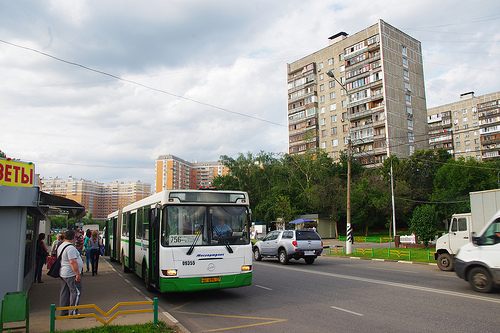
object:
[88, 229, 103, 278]
person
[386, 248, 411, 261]
fence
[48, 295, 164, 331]
fence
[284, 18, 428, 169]
building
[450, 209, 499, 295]
car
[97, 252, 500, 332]
street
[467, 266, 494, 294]
tire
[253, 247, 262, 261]
tire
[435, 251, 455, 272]
tire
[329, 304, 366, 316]
line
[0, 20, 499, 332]
city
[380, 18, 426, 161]
wall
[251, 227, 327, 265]
car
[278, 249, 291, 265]
tire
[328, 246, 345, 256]
fence section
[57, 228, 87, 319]
person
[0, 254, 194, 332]
sidewalk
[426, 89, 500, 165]
building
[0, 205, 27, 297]
wall